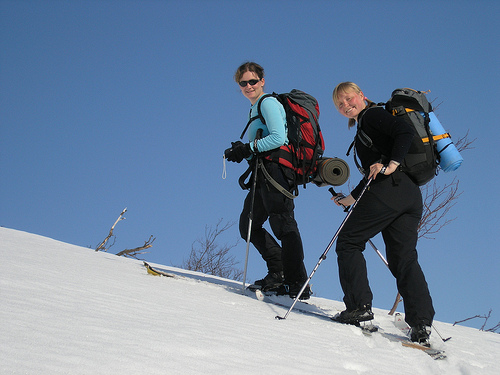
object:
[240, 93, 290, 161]
shirt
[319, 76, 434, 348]
woman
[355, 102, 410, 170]
shirt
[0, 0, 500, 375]
scene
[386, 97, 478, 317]
trees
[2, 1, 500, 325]
sky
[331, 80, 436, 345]
lady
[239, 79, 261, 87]
sunglasses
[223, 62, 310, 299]
skiers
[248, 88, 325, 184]
backpack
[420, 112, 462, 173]
bed mat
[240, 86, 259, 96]
smiling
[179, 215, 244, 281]
bare branch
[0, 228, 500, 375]
ground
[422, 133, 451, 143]
orange straps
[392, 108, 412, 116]
orange straps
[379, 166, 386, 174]
strap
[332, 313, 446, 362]
tracks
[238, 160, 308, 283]
pants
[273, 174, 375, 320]
pole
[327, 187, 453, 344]
pole